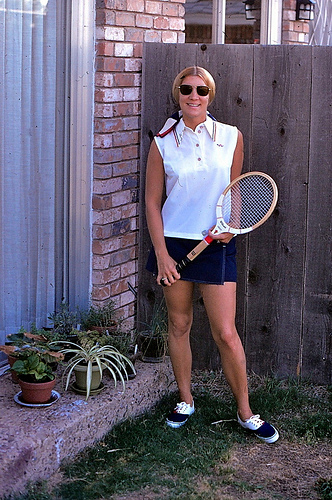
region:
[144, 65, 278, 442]
female tennis player with short blond hair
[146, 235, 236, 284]
short dark blue tennis skirt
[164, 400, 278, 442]
blue and white tennis shoes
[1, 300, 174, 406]
a collection of various potted house plants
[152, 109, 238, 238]
white sleeveless shirt with pointy collar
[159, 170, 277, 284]
light brown wilson tennis racket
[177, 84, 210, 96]
tinted wire framed aviator shades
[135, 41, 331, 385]
weathered grey wood fence with wide planks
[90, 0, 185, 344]
weathered looking red and white bricks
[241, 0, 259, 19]
reflection of black metal exterior light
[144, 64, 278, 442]
Girl holding a tennis racquet.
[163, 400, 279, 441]
The girl is wearing blue and white shoes.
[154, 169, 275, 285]
Brown and white tennis racquet with a black handle.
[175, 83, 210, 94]
The girl wearing dark sunglasses.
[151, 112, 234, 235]
The girl is wearing a white shirt.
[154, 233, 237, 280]
The girl is wearing a blue skirt.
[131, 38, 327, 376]
Brown wooden fence behind the girl.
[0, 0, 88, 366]
Sliding glass door next to the girl.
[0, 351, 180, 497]
Concrete stoop in front of the door.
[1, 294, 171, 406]
Potted plants on top of the door stoop.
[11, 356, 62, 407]
Potted plant sitting on the step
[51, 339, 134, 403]
Spider plant sitting on the step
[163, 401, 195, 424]
White and black sneaker on the girl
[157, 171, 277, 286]
Sport racket being held by girl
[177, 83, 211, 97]
Sunglasses being worn by girl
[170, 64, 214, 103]
Blond hair on the girl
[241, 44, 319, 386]
Wood fence post behind girl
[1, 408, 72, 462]
Pebbled cement step holding the potted plants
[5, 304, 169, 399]
Eight potted plants sitting on the step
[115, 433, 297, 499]
Patchy grass in front of the girl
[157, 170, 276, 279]
The tennis racket in the lady's hands.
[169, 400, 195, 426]
The left sneaker of the lady.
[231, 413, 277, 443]
The right sneaker of the lady.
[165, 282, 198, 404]
The left leg of the lady.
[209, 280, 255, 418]
The right leg of the lady.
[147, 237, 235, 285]
The skirt the lady is wearing.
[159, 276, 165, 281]
The ring on the lady's left hand.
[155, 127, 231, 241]
The white tank top the lady is wearing.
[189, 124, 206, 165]
The buttons on the lady's tank top.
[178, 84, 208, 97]
The sunglasses the lady is wearing.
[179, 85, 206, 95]
Black sunglasses a a persons face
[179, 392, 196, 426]
blue and white shoes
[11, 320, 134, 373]
A bunch of potted plants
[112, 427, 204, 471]
Dark green grass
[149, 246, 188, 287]
A person wearing a ring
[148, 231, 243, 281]
A person in a blue skirt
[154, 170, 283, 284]
A person with a tennis racket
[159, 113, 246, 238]
A person in a white polo shirt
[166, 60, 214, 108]
A person with blond hair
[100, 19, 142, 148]
A red brick wall